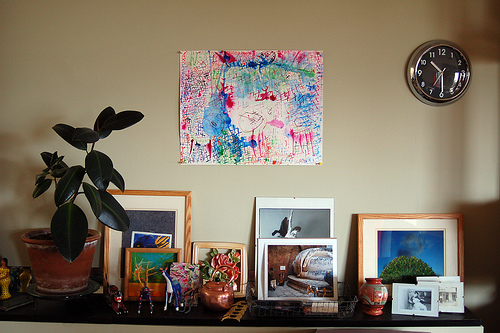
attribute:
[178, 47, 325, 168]
drawing — bad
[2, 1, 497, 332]
wall — beige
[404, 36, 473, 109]
clock — chrome, industrial, silver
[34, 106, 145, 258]
plant — large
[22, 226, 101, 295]
pot — terracotta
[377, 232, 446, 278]
photograph — blue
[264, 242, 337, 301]
photograph — large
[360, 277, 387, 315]
vase — small, rust brown, miniature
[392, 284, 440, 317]
photograph — black, white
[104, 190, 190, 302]
frame — wooden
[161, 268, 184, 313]
giraffe toy — small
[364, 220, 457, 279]
card stock matt — white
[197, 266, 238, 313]
tea pot — copper, brass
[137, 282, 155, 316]
animal — handmade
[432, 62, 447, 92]
clock hands — white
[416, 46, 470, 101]
clock face — black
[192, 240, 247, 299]
frame — wooden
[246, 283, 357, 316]
wire basket — silver, gray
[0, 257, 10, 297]
woman figurine — yellow